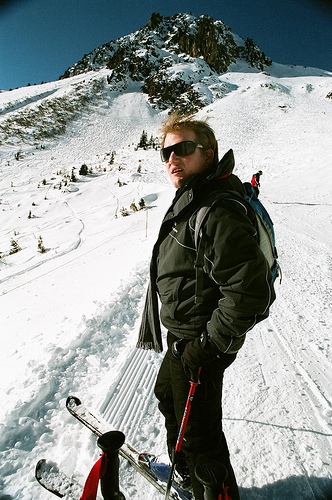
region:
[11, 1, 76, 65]
The sky is clear and blue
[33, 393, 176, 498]
The man is wearing skis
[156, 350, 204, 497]
The man is holding a ski stick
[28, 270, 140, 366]
The color of the snow is white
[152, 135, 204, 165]
The man is wearing sun glasses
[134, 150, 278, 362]
The man is wearing a jacket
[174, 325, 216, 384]
The man is wearing gloves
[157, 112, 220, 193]
The head of the man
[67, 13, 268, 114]
The mountain is covered in snow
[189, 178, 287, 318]
The man is wearing a back pack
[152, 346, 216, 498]
A red and black ski pole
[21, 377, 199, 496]
A pair of skis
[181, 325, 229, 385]
Black winter gloves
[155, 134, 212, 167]
A pair of black sunglasses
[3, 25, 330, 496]
White snow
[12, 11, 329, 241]
Snow on the mountain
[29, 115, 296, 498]
A man standing in skis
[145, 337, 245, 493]
A pair of black winter pants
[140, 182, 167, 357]
A dark grey scarf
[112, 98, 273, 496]
this is a man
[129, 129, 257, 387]
man wearing a black jacket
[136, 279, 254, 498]
man wearing black pants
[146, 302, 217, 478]
man holding a ski pole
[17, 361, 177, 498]
this is a set of skis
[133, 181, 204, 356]
man wearing a scarf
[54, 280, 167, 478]
ski tracks in snow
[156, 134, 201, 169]
pair of black sunglasses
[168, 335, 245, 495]
the ski pole is red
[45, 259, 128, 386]
snow covering the ground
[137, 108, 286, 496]
man with skiing gear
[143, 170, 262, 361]
man wearing a black jacket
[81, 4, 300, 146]
large snowy mountain range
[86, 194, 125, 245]
area of white snow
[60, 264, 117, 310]
area of white snow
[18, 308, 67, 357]
area of white snow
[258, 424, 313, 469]
area of white snow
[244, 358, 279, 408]
area of white snow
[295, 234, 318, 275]
area of white snow